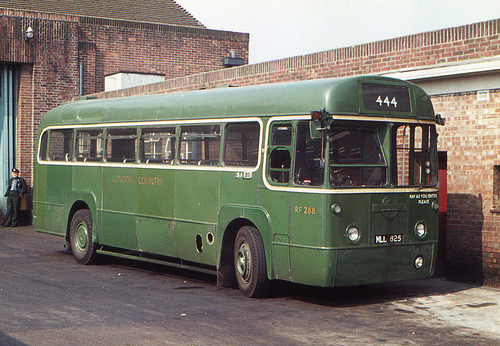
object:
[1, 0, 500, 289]
building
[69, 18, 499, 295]
building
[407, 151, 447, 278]
door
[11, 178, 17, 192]
shirt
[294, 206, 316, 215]
word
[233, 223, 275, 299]
tire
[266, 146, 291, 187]
window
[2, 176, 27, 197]
jacket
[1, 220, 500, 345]
road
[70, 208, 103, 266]
tire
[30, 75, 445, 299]
bus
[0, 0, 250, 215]
building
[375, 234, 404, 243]
plate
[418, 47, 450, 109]
ground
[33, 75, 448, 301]
buttons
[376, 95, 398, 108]
numbers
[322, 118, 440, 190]
windshield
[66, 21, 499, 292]
wall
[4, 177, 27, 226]
uniform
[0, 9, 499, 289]
bricks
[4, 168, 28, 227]
guard